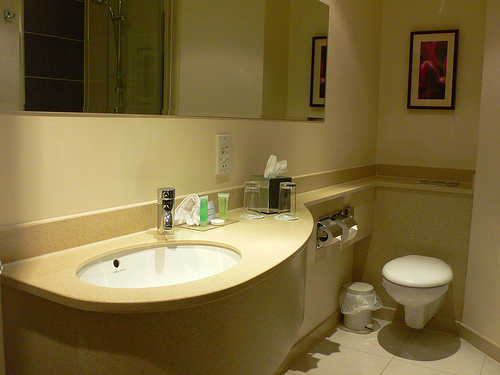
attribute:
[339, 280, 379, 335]
trash can — small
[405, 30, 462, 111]
frame — picture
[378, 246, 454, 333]
toilet — white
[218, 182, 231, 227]
bottle — green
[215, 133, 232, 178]
outlet — white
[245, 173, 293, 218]
box — tissue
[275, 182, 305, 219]
cup — upside-down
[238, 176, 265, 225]
cup — upside-down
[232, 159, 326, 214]
tissues — box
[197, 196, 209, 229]
bottle — small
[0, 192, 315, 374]
counter — clean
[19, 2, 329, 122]
mirror — large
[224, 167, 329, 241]
cup — upside-down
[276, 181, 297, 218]
glass — clear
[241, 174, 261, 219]
glass — clear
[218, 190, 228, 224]
bottle — small